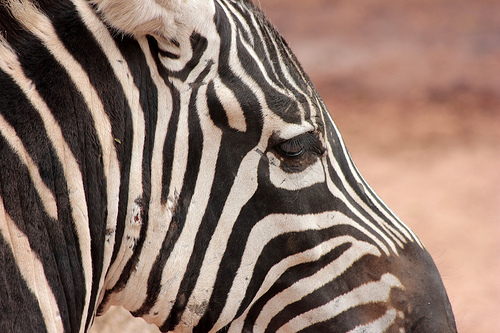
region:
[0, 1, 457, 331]
The zebra is striped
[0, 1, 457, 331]
Zebra near the camera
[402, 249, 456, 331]
Front of face is black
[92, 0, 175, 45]
The ear is furry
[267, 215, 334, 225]
Patch of white fur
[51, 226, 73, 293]
Patch of black fur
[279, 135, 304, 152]
Eye ball is brown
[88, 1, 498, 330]
The surroundings are arid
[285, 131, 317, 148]
Eye lashes are black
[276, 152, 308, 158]
Eye lid is black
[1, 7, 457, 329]
up close view of a zebra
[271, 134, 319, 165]
right eye of the zebra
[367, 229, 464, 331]
nose of the zebra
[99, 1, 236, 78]
right ear of the zebra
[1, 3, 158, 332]
neck of the zebra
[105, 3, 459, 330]
head of the zebra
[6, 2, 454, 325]
zebra looking onward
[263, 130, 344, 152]
the zebra's eye is open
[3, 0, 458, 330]
profile view of a zebra's head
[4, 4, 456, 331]
zoomed in view of a zebra's head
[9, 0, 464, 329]
the head of a zebra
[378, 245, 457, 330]
black nose of the zebra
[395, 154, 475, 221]
brown dirt of the ground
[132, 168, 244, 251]
black and white stripes of the zebra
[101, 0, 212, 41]
white hairy ear of the zebra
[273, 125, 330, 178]
black eye of the zebra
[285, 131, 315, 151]
black lashes over the zebra's eye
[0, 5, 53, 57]
black and white mane of the zebra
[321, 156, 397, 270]
black and white face of the zebra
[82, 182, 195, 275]
scars on the zebra's neck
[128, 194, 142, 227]
wound on the side of a zebra's neck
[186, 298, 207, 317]
patch of skin missing hair on face of zebra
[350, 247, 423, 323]
brown dirt on zebra's nose area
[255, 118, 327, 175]
black and white are around zebra's eye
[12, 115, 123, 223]
black and white stripes on a zebra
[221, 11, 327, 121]
black and white stripes on forehead of zebra's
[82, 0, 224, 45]
earlobe on a zebra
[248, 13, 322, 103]
dirt on forehead of a zebra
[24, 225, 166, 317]
wrinkles in the neck area of zebra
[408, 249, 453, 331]
black nose area of a zebra